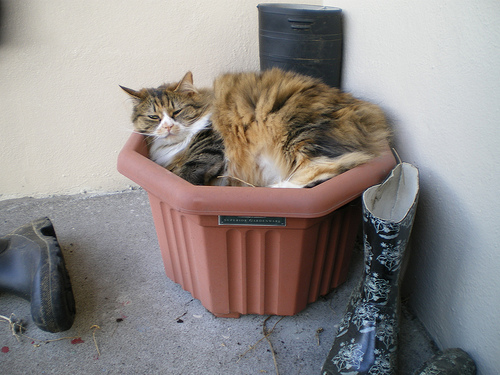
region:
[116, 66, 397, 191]
a cat laying down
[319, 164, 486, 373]
a black and white boot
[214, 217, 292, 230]
a label on holder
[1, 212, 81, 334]
a black boot laying down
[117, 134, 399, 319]
a holder itself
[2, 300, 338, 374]
twigs on the ground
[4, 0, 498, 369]
a tan wall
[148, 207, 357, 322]
imprint on tub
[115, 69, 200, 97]
pointy ears on cat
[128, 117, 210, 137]
whiskers on face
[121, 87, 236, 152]
a cat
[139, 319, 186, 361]
the ground is grey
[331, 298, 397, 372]
boots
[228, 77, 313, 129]
the cats fur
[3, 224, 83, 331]
the boot on ground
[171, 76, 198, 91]
the cats ear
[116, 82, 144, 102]
the cats right ear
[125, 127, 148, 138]
the cats whiskers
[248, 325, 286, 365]
sticks on the ground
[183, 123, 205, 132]
the cats whiskers are white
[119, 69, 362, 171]
large striped cat laying down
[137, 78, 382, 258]
large striped cat laying in a pot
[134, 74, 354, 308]
cat in a flower pot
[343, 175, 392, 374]
floral pattern rubber boot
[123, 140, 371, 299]
large orange flower pot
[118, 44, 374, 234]
cat resting in a flower pot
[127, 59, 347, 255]
cat laying down outside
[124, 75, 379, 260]
feline in a pot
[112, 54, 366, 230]
big cat in a orange pot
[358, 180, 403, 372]
boot next to a flower pot with cat in it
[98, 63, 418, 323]
two cats in a basket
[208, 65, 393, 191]
cat is color brown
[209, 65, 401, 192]
cat has long fur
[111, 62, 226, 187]
car is brown and black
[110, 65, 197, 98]
pointy ears of cat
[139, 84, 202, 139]
face is gray and white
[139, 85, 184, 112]
black stripes on head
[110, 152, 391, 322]
the basket color red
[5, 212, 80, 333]
the boot is color black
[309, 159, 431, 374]
boot is color black and white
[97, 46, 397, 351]
cat laying in a flower pot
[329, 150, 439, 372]
rubber rain boot with white floral design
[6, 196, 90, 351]
plain black boot with dirt on it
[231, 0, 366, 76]
top of a plain black boot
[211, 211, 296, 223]
small label mounted to the plant pot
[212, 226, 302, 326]
three dimensional design in the pot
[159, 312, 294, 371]
dirt and twigs on the cement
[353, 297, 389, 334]
white floral design on the black boot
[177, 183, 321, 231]
lip of the rust colored pot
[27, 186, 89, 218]
area where the wall meets the concrete